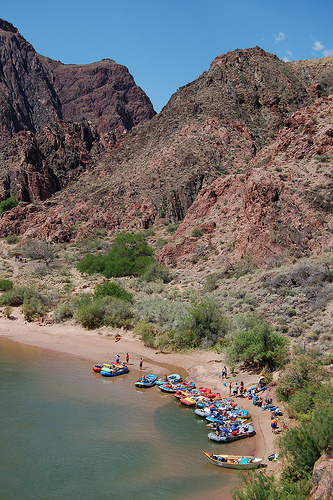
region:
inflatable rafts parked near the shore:
[91, 356, 250, 457]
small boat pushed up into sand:
[200, 448, 266, 476]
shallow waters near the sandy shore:
[73, 435, 192, 493]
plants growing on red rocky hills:
[68, 186, 303, 321]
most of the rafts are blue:
[94, 356, 249, 452]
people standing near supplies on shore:
[214, 362, 257, 410]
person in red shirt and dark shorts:
[122, 346, 132, 369]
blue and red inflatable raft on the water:
[131, 368, 156, 393]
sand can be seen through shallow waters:
[122, 417, 183, 481]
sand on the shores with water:
[14, 312, 93, 367]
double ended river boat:
[200, 449, 263, 470]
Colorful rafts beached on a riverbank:
[88, 350, 255, 444]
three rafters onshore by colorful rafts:
[113, 350, 145, 368]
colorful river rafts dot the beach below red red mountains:
[1, 2, 331, 496]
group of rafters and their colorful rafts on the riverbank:
[93, 329, 288, 466]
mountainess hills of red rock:
[0, 12, 330, 257]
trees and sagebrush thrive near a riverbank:
[1, 230, 331, 498]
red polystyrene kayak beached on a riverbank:
[113, 335, 122, 342]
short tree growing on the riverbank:
[153, 334, 172, 355]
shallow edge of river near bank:
[2, 337, 267, 497]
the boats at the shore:
[87, 360, 132, 386]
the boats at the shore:
[133, 352, 261, 464]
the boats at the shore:
[182, 391, 272, 499]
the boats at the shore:
[167, 378, 231, 447]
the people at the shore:
[192, 359, 255, 406]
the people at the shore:
[243, 385, 304, 451]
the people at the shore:
[214, 356, 269, 413]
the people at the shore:
[233, 370, 276, 441]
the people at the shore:
[96, 340, 156, 368]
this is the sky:
[129, 9, 163, 38]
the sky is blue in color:
[122, 9, 157, 28]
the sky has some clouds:
[291, 30, 327, 53]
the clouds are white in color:
[275, 29, 323, 53]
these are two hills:
[30, 35, 281, 307]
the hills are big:
[4, 22, 316, 475]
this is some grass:
[199, 320, 228, 349]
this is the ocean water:
[9, 405, 148, 481]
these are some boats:
[86, 349, 281, 473]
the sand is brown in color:
[196, 358, 209, 369]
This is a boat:
[199, 449, 266, 472]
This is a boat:
[204, 424, 259, 444]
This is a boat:
[201, 416, 257, 428]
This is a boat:
[198, 408, 263, 422]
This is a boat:
[190, 397, 244, 417]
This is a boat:
[178, 391, 235, 408]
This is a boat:
[171, 385, 221, 398]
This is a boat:
[151, 379, 207, 389]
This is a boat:
[149, 371, 186, 385]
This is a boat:
[132, 366, 158, 402]